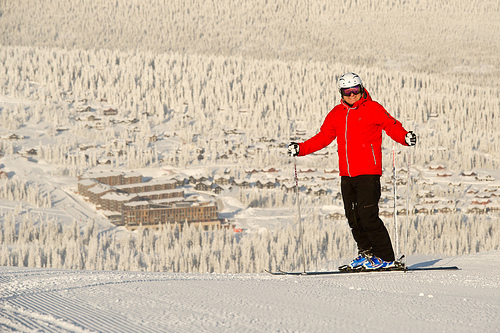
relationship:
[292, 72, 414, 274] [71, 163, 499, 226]
person skiing above town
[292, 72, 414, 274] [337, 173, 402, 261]
person has pants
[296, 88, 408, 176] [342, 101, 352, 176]
jacket with zippers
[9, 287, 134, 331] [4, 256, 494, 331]
straight lines in snow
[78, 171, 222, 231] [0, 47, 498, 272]
buildings among trees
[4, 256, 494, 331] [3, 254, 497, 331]
snow on ground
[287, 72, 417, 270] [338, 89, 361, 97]
person wearing glasses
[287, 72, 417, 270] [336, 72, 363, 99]
person wearing helmet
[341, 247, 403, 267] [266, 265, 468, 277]
ski boots on skis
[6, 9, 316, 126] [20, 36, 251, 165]
trees covered in snow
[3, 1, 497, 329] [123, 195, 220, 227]
snow covering tall building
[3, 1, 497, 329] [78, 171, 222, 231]
snow covering buildings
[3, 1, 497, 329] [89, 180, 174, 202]
snow covering tall building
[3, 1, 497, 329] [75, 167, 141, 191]
snow covering tall building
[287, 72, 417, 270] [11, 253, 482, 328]
person standing on mountaintop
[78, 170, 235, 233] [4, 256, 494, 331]
buildings covered in snow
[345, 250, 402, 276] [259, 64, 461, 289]
ski boots on skier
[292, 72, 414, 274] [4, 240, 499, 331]
person on top of mountain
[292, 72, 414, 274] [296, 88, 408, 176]
person dressed in jacket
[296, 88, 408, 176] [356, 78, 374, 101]
jacket with hood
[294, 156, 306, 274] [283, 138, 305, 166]
pole in hand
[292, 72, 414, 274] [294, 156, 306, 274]
person holding pole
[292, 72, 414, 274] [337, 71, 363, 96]
person wearing helmet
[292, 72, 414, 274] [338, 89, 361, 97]
person wearing glasses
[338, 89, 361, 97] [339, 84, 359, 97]
glasses over eyes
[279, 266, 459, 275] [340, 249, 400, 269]
skis attached to feet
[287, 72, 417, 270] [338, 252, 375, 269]
person wearing ski boots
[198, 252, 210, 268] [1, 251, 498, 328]
tree at bottom of mountain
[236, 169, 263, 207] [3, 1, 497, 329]
tree in snow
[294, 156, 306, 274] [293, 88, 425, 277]
pole of skier